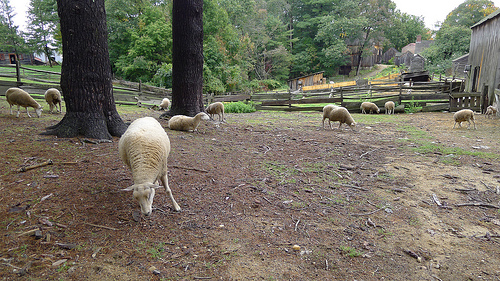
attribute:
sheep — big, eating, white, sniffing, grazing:
[119, 116, 181, 216]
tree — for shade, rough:
[40, 0, 127, 138]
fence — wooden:
[1, 61, 468, 112]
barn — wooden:
[463, 9, 499, 109]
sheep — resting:
[168, 112, 211, 133]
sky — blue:
[395, 0, 499, 23]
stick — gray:
[20, 159, 54, 173]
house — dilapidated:
[1, 47, 44, 65]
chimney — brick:
[415, 34, 422, 43]